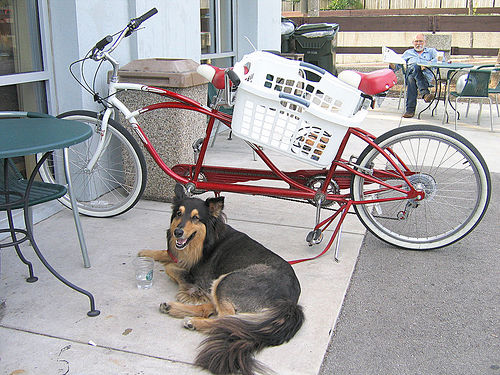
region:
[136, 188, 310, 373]
Dog laying on the ground.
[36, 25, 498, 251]
Bicycle parked on the walk.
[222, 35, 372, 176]
white basket on bike.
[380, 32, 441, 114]
man reading a newspaper.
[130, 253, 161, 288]
cup of water on the walk.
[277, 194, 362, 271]
Red leash on bike.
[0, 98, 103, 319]
Green patio table on walk.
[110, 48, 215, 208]
Brown trash can on walk.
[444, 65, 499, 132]
Chair in the background.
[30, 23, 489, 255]
Two seats on the bicycle.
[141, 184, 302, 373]
black and brown collie on the ground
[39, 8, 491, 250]
red and white bicycle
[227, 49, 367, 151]
white plastic basket on bike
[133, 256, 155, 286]
clear cup of water for the dog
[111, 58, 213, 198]
trash can next to the bike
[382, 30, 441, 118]
old man reading a newspaper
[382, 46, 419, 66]
the newspaper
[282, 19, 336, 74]
green trash cans in the background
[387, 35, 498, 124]
man sitting alone at a table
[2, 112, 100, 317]
green table and chair by the dog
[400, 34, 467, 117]
man sitting at table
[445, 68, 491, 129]
back of green chair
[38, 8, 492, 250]
bicycle built for two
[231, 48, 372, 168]
while basket with handles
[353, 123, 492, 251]
tire with white wall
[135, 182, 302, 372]
dog laying on cement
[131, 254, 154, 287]
cup of water on ground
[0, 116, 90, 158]
top of green table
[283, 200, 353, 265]
dog leash on bike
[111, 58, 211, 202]
trash can with lid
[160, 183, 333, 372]
the dog is sitting on the ground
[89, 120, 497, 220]
a red and white bike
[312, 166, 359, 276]
the bike has a kickstand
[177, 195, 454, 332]
the leash is on the dog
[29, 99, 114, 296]
the table is green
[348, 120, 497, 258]
the tires have white walls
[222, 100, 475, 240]
the basket is white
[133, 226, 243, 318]
the brown and balck collie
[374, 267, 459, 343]
the cement is gray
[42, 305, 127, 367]
the sidewalk is lighter colored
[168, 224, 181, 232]
Dog has black nose.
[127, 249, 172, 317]
Cup of water in front of dog.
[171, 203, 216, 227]
Dog has dark eyes.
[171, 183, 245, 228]
Dog has brown and black ears.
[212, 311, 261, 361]
Dog has long tail.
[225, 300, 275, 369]
Dog has black and brown tail.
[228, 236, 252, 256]
Dog has black back.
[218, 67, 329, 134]
White basket sitting on bike.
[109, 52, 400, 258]
Tandem bike parked on sidewalk.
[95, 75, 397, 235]
Bike is red and white.